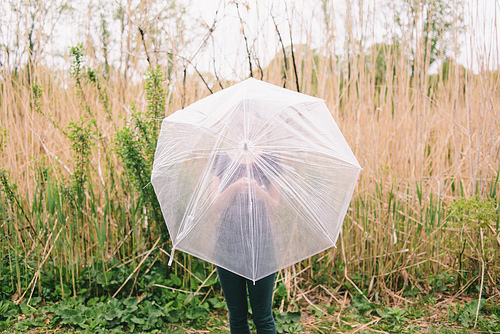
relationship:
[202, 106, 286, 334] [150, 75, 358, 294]
girl held umbrella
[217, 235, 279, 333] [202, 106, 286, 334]
jeans on girl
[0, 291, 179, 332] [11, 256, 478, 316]
plant on ground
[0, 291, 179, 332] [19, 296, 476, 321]
plant on ground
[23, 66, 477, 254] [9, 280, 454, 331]
plant on ground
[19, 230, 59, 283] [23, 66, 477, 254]
sticks on plant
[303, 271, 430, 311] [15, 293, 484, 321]
twig on ground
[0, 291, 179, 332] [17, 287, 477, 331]
plant on ground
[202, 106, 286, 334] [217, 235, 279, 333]
girl has jeans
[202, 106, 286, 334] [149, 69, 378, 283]
girl holding umbrella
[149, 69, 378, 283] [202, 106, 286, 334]
umbrella protecting girl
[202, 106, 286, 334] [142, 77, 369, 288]
girl with umbrella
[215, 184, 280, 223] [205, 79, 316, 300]
arm on woman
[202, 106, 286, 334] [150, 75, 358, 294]
girl under umbrella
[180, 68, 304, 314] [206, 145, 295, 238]
girl wearing shirt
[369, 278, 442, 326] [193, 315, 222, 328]
weeds on ground